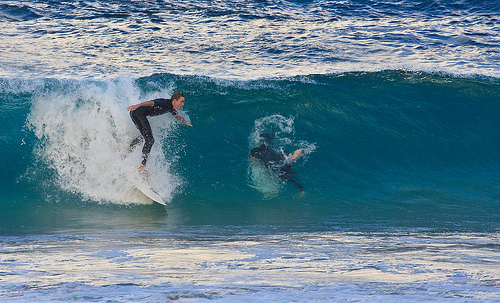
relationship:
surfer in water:
[119, 88, 192, 157] [197, 136, 233, 200]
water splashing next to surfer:
[197, 136, 233, 200] [119, 88, 192, 157]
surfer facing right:
[119, 88, 192, 157] [153, 90, 200, 111]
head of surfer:
[160, 82, 196, 118] [119, 88, 192, 157]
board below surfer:
[115, 154, 181, 215] [119, 88, 192, 157]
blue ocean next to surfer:
[382, 108, 453, 185] [119, 88, 192, 157]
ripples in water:
[49, 57, 116, 119] [197, 136, 233, 200]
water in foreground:
[197, 136, 233, 200] [201, 182, 311, 295]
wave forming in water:
[49, 57, 116, 119] [197, 136, 233, 200]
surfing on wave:
[101, 145, 203, 184] [15, 62, 361, 152]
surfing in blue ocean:
[101, 145, 203, 184] [326, 96, 499, 186]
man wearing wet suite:
[119, 88, 192, 157] [130, 88, 187, 130]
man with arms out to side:
[137, 81, 230, 189] [125, 96, 171, 128]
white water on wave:
[41, 118, 132, 162] [15, 62, 361, 152]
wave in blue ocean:
[15, 62, 361, 152] [326, 96, 499, 186]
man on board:
[137, 81, 230, 189] [115, 154, 181, 215]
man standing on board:
[137, 81, 230, 189] [115, 154, 181, 215]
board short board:
[118, 146, 169, 207] [115, 154, 181, 215]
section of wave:
[202, 99, 244, 125] [15, 62, 361, 152]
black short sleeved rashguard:
[130, 88, 187, 130] [117, 114, 180, 153]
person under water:
[194, 116, 340, 182] [197, 136, 233, 200]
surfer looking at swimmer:
[119, 88, 192, 157] [246, 127, 304, 177]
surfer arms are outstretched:
[119, 88, 192, 157] [130, 88, 187, 130]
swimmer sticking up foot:
[246, 127, 304, 177] [280, 149, 314, 161]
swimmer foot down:
[246, 127, 304, 177] [261, 114, 309, 173]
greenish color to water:
[392, 89, 469, 158] [197, 136, 233, 200]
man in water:
[137, 81, 230, 189] [197, 136, 233, 200]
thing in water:
[235, 119, 277, 148] [197, 136, 233, 200]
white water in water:
[53, 86, 131, 200] [197, 136, 233, 200]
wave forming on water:
[15, 62, 361, 152] [197, 136, 233, 200]